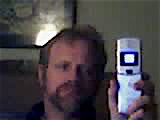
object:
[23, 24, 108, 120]
man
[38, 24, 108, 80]
hair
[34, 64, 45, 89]
ear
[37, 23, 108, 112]
head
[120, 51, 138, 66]
display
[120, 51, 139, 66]
rectangle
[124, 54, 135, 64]
light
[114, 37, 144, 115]
phone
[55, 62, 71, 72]
eye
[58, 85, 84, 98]
mouth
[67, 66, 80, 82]
nose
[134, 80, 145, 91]
finger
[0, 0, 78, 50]
picture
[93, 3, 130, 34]
wall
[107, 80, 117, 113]
thumb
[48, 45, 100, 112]
face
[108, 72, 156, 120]
hand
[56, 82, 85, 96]
mustache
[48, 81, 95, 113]
beard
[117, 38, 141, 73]
screen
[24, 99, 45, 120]
tee